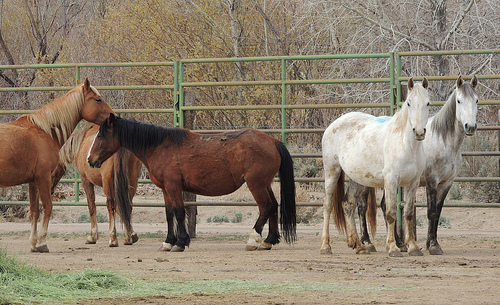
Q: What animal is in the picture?
A: Horses.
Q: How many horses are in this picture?
A: 5.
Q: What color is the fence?
A: Green.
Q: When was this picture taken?
A: Daytime.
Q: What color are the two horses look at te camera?
A: White.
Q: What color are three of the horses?
A: Brown.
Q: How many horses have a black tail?
A: 1.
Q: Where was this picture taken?
A: Horse ranch.